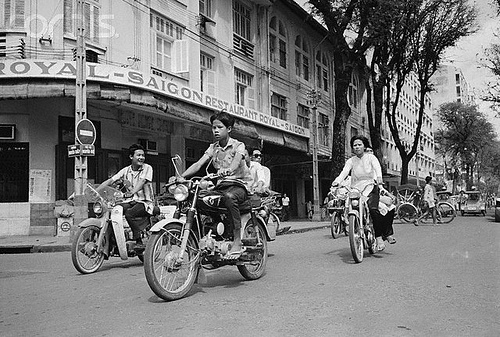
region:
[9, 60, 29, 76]
black letter on sign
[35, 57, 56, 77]
black letter on sign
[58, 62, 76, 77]
black letter on sign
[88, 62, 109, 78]
black letter on sign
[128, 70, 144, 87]
black letter on sign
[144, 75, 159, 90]
black letter on sign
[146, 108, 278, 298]
A boy on a motorcycle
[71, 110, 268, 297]
Two boys riding motorcyles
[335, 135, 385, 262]
A woman on a motorcycle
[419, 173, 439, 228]
A person walking in the street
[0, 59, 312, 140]
A restraunt sign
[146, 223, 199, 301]
A motorcycle wheel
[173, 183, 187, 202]
A motorcycle head light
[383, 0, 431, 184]
A tree with three branches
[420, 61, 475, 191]
A building in background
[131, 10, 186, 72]
Large window on a building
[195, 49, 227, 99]
Large window on a building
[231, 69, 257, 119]
Large window on a building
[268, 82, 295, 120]
Large window on a building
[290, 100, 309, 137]
Large window on a building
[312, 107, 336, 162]
Large window on a building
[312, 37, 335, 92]
Large window on a building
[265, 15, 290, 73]
Large window on a building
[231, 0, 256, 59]
Large window on a building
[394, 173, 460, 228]
person walking bike across road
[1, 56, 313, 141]
long banner style restaurant sign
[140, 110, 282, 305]
boy leading group of bikes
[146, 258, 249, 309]
shadow of bike on road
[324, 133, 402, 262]
person wearing all white shirt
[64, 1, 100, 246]
tall street light post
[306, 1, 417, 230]
tall tree with thick trunk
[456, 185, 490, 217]
car parked with trunk open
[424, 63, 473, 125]
white building with long rectangular windows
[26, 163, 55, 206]
poster with writing on corner of building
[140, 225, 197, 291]
The front tire of the motorcycle in the middle.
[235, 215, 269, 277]
The back tire of the motorcycle in the middle.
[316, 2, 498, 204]
The trees in the background.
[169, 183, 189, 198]
The headlight of the motorcycle in the middle.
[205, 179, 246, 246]
The pants of the person riding the motorcycle in the middle.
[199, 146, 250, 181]
The shirt of the person riding the motorcycle in the middle.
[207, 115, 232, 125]
The short hair of the person riding the motorcycle in the middle.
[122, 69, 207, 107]
The word SAIGON on the building.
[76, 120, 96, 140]
The circle shaped sign on the pole.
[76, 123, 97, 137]
The white stripe on the circle shaped sign on the pole.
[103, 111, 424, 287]
many people on bikes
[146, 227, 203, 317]
dark wheel on bike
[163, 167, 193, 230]
round headlight on bike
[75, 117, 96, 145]
the sign is circular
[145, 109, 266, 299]
the person is the bike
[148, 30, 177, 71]
A window on a building.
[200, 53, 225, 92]
A window on a building.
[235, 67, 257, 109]
A window on a building.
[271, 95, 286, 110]
A window on a building.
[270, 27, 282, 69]
A window on a building.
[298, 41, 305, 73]
A window on a building.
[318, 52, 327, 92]
A window on a building.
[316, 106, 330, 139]
A window on a building.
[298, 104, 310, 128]
A window on a building.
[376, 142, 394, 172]
A window on a building.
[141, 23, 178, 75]
A window on a building.